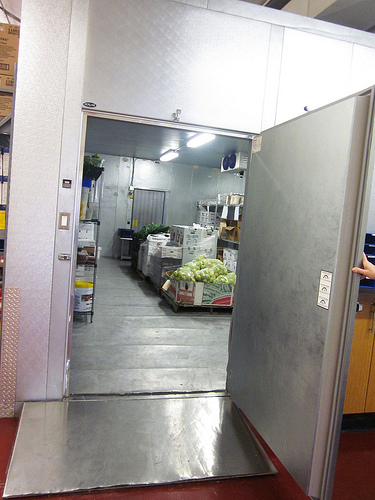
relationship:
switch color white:
[59, 208, 70, 230] [57, 212, 71, 227]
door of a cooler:
[224, 82, 373, 499] [78, 104, 247, 398]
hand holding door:
[350, 252, 373, 282] [224, 82, 373, 499]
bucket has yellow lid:
[74, 278, 95, 314] [75, 278, 96, 288]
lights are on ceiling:
[155, 125, 219, 165] [89, 122, 231, 169]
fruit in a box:
[165, 255, 234, 290] [161, 279, 236, 311]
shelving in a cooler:
[75, 216, 100, 326] [78, 104, 247, 398]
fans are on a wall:
[216, 145, 246, 178] [168, 158, 245, 204]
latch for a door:
[356, 296, 367, 317] [224, 82, 373, 499]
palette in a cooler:
[165, 304, 240, 312] [78, 104, 247, 398]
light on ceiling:
[155, 125, 219, 165] [89, 122, 231, 169]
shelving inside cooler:
[195, 190, 245, 263] [78, 104, 247, 398]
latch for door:
[356, 296, 367, 317] [224, 82, 373, 499]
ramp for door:
[9, 394, 280, 492] [224, 82, 373, 499]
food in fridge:
[165, 255, 234, 290] [78, 104, 247, 398]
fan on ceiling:
[216, 145, 246, 178] [89, 122, 231, 169]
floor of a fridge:
[73, 322, 224, 388] [78, 104, 247, 398]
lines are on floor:
[95, 297, 189, 390] [73, 322, 224, 388]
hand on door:
[350, 252, 373, 282] [224, 82, 373, 499]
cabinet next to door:
[358, 231, 373, 290] [224, 82, 373, 499]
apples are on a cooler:
[165, 255, 234, 290] [78, 104, 247, 398]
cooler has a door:
[78, 104, 247, 398] [224, 82, 373, 499]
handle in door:
[356, 296, 367, 317] [224, 82, 373, 499]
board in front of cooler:
[9, 394, 280, 492] [78, 104, 247, 398]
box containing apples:
[161, 279, 236, 311] [165, 255, 234, 290]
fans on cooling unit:
[216, 145, 246, 178] [23, 10, 373, 468]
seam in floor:
[75, 338, 224, 359] [73, 322, 224, 388]